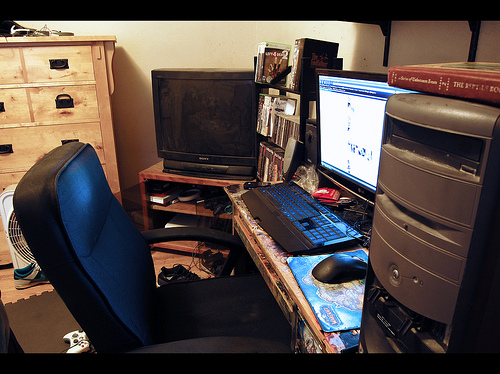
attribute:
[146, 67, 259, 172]
set — Tube television 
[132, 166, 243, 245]
stand — wooden TV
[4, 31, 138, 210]
chest — Blonde wood c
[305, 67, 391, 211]
monitor — Powered up computer 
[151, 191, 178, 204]
games — video 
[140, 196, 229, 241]
rack — Media 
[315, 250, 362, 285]
mouse — Black computer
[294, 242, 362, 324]
pad — mouse 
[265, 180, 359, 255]
keyboard — Computer 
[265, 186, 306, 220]
keys — blue 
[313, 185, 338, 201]
book — Hard bound 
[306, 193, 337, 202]
spine — red 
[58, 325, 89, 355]
controller — White Xbox 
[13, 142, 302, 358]
chair — Black leather swivel desk,  black desk , very cushioned office 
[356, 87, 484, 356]
tower — Black CPU  ,  foreground., black desk top computer 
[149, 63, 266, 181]
set — black tv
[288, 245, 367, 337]
pad — mouse 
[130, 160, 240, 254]
stand — wooden tv 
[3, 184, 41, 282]
fan — white box 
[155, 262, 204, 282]
shoe —  black athletic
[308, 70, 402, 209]
monitor — computer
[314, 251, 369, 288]
mouse — black computer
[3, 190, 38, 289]
fan — white 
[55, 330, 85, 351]
control — video console remote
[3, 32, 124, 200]
dresser — wood 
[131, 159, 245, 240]
stand — wood TV s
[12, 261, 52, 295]
sneaker — blue, white, black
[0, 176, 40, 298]
fan — white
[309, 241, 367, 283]
mouse — black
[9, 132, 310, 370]
chair — black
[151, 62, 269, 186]
tv — black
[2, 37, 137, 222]
dresser — light wood , brown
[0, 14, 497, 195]
wall — white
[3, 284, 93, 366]
mat — black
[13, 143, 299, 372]
desk chair — black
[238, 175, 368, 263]
keyboard — black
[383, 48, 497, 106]
book — red, hard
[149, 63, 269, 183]
tv set — black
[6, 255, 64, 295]
sneaker — white, blue